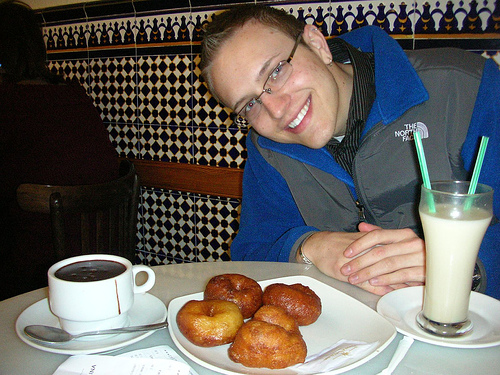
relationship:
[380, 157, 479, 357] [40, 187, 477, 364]
milk on table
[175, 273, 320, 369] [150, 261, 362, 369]
donuts on plate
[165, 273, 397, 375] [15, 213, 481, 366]
plate on table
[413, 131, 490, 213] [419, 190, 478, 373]
straws in milk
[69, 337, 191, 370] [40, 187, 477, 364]
slips on table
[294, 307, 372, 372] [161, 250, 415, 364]
packet on plate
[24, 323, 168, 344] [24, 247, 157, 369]
spoon on plate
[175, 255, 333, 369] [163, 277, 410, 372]
donuts on plate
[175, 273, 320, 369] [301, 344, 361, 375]
donuts on plate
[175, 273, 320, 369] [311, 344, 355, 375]
donuts on plate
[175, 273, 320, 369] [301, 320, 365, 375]
donuts on plate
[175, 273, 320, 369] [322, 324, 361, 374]
donuts on plate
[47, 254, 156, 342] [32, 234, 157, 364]
cup of chocolate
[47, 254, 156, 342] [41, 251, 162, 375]
cup of chocolate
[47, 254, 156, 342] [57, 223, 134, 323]
cup of chocolate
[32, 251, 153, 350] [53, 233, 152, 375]
cup of chocolate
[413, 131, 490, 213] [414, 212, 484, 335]
straws in a glass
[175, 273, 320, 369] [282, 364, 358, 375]
donuts on a plate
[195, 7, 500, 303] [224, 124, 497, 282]
man sitting in a chair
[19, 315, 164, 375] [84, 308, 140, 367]
spoon on a small plate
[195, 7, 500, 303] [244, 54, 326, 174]
man guy smiling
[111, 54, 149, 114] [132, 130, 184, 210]
tiles on wall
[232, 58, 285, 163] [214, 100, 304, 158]
nose on guys face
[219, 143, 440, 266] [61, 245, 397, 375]
man sitting by table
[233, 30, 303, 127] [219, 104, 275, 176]
eyeglasses on mans face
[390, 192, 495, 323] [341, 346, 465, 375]
glass on table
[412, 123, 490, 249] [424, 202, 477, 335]
straws in glass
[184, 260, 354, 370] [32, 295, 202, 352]
plate on table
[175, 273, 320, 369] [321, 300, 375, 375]
donuts on plate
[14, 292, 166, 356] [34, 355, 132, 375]
plate on table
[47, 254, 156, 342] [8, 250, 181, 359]
cup on saucer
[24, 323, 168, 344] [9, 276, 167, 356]
spoon on saucer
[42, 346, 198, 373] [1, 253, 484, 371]
receipt on table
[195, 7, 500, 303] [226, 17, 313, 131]
man wearing glasses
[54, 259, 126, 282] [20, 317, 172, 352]
chocolate with spoon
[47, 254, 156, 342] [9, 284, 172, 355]
cup on saucer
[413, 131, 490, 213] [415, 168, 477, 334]
straws in glass